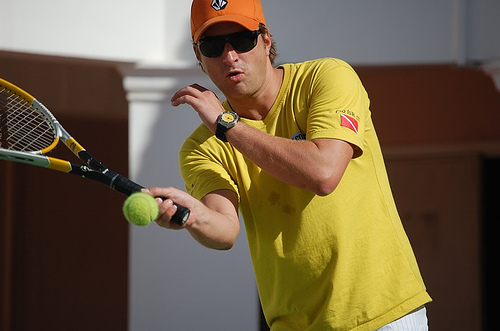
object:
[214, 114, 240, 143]
wrist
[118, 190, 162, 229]
ball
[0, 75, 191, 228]
racket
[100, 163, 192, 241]
handle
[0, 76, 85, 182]
head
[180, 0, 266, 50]
cap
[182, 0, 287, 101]
head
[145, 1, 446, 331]
man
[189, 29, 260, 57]
sunglasses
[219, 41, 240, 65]
nose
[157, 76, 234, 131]
hand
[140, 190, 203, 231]
hand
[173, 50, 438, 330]
shirt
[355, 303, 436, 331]
pants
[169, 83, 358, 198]
arm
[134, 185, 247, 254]
arm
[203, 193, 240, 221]
bicep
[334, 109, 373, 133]
logo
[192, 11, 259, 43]
front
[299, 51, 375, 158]
sleeves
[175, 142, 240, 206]
sleeves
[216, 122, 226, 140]
band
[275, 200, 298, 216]
spots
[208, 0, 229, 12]
emblem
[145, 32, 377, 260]
player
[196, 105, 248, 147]
watch